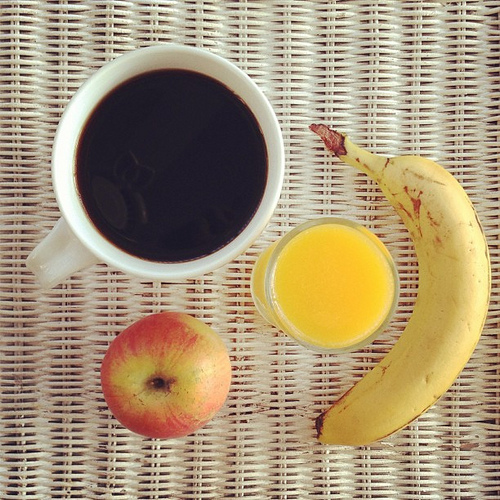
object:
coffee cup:
[25, 43, 285, 290]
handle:
[25, 215, 99, 290]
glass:
[250, 217, 402, 354]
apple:
[100, 312, 232, 439]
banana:
[309, 123, 493, 444]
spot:
[315, 413, 325, 439]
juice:
[254, 224, 394, 348]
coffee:
[75, 69, 269, 262]